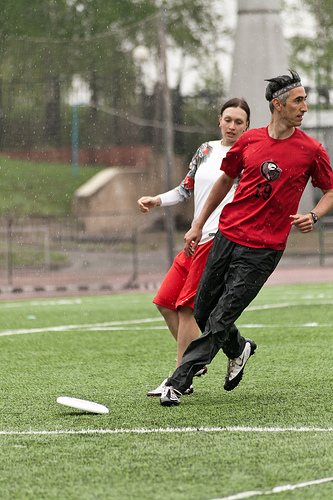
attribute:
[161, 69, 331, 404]
man — looking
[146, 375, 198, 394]
cleat — right woman's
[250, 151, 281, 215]
logo —  team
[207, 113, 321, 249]
shirt — man's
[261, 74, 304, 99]
hair — wet, dark, gray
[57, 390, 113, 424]
frisbee — landing, white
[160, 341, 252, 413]
shoe — black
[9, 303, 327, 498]
line — painted, white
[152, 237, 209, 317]
shorts — red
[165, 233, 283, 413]
pant — black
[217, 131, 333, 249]
shirt — red, team logo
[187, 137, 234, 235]
shirt — white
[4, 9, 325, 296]
rain drops — falling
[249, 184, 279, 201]
number — 19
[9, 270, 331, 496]
in  a field — green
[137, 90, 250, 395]
woman — playing